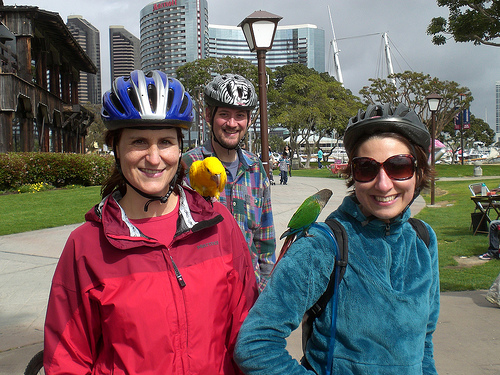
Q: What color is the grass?
A: Green.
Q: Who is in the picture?
A: 3 people.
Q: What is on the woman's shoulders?
A: Birds.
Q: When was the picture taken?
A: In the daytime.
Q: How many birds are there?
A: 2.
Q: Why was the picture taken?
A: To show the birds.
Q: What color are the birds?
A: Green and yellow.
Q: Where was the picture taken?
A: In a park.